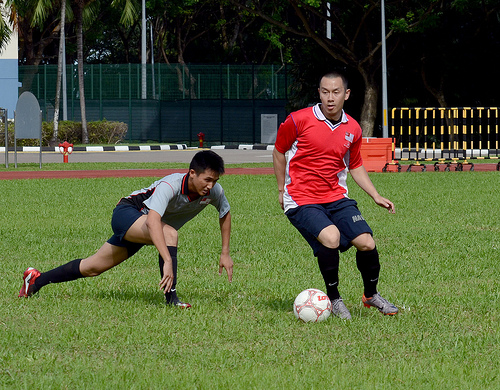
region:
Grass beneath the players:
[1, 170, 497, 389]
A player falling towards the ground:
[20, 151, 232, 307]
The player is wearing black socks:
[35, 258, 80, 291]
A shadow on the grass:
[44, 290, 164, 302]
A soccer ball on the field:
[293, 289, 330, 320]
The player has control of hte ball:
[271, 72, 399, 319]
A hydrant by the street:
[58, 141, 70, 161]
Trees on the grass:
[7, 4, 136, 139]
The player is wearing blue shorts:
[284, 195, 371, 249]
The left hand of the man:
[376, 196, 394, 213]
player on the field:
[269, 68, 413, 334]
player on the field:
[0, 147, 245, 339]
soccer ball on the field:
[278, 281, 339, 334]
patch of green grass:
[214, 347, 248, 377]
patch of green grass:
[397, 322, 434, 361]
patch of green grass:
[200, 310, 228, 342]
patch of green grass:
[84, 319, 136, 356]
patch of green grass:
[430, 277, 474, 311]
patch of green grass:
[430, 217, 463, 247]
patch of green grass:
[80, 330, 117, 364]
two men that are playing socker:
[22, 74, 410, 329]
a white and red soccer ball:
[289, 284, 334, 325]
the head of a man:
[179, 149, 226, 202]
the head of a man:
[309, 67, 357, 122]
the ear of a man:
[186, 165, 198, 180]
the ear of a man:
[342, 82, 353, 106]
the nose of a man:
[324, 87, 337, 106]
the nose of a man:
[203, 178, 218, 194]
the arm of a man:
[143, 184, 181, 295]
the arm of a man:
[212, 188, 246, 286]